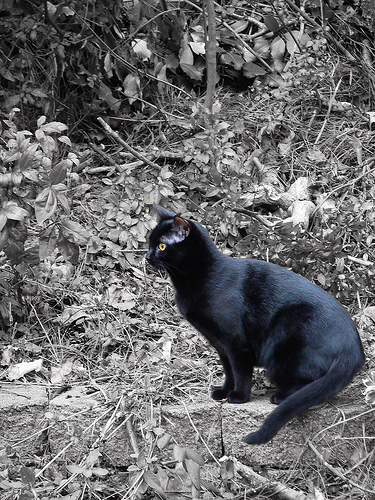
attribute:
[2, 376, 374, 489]
wall — concrete, stone, cement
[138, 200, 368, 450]
cat — black, shiny, sitting, looking left, shiny black, looking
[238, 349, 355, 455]
tail — long, black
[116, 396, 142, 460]
branches — hanging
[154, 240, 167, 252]
eye — yellow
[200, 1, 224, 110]
trunk — thin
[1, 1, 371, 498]
photo — black, white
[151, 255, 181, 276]
whiskers — white